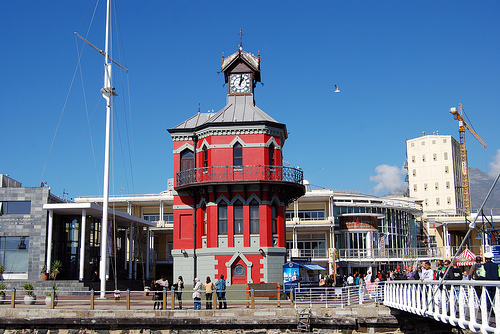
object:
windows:
[232, 140, 244, 168]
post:
[479, 286, 487, 327]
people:
[404, 266, 418, 279]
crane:
[449, 103, 488, 215]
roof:
[218, 51, 262, 98]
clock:
[229, 74, 252, 94]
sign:
[284, 263, 299, 284]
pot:
[44, 295, 59, 307]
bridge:
[383, 278, 500, 333]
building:
[165, 26, 306, 291]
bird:
[333, 84, 341, 93]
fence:
[385, 281, 500, 333]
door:
[230, 256, 249, 284]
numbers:
[245, 86, 249, 89]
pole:
[98, 0, 114, 298]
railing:
[380, 279, 500, 287]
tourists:
[192, 277, 203, 310]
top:
[218, 44, 262, 105]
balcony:
[174, 165, 304, 192]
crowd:
[312, 252, 499, 299]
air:
[1, 0, 500, 213]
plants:
[18, 282, 36, 298]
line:
[0, 298, 291, 302]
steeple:
[220, 25, 262, 105]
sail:
[72, 0, 133, 296]